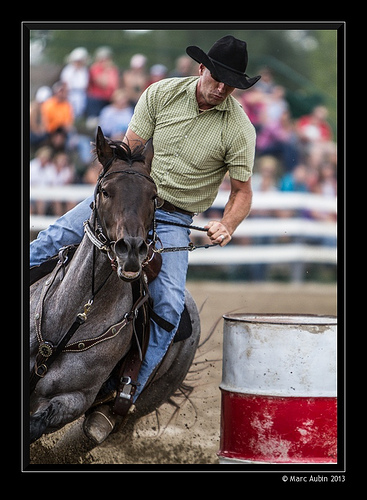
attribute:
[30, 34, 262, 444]
man — light skinned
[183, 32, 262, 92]
hat — black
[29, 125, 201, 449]
horse — brown, gray, fast, running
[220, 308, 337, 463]
drum — red, white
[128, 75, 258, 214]
shirt — green, plaid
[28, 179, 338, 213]
rail — white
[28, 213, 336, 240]
rail — white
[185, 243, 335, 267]
rail — white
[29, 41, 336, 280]
spectators — sitting in stands, watching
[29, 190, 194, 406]
jeans — blue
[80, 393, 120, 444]
boot — dark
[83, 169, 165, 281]
straps — black